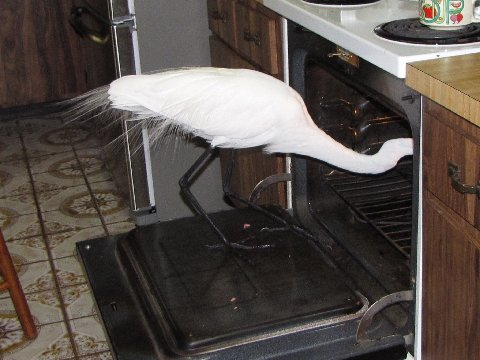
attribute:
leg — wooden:
[0, 229, 38, 342]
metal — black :
[446, 164, 478, 196]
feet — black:
[164, 172, 341, 255]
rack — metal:
[329, 164, 418, 253]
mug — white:
[415, 1, 478, 31]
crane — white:
[47, 65, 410, 257]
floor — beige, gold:
[49, 295, 94, 345]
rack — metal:
[347, 187, 416, 235]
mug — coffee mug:
[406, 0, 478, 34]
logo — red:
[421, 2, 438, 19]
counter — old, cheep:
[405, 45, 479, 350]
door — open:
[71, 202, 411, 358]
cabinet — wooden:
[419, 194, 478, 352]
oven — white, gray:
[65, 15, 424, 358]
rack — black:
[317, 161, 417, 257]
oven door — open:
[72, 204, 401, 356]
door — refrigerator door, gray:
[63, 0, 165, 216]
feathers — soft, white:
[49, 82, 211, 161]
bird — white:
[58, 66, 414, 255]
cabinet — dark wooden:
[191, 38, 290, 209]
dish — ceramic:
[417, 0, 479, 28]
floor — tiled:
[17, 141, 71, 222]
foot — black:
[223, 218, 267, 241]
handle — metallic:
[52, 6, 110, 50]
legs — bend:
[170, 146, 314, 261]